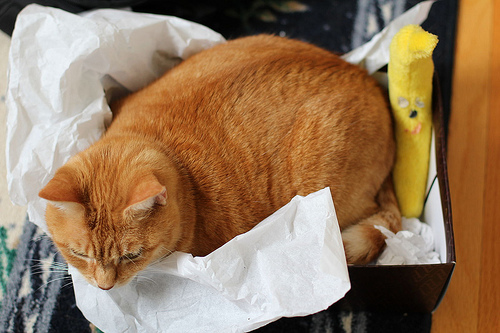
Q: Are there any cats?
A: Yes, there is a cat.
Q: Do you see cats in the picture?
A: Yes, there is a cat.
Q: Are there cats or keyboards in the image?
A: Yes, there is a cat.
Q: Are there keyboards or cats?
A: Yes, there is a cat.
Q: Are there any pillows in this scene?
A: No, there are no pillows.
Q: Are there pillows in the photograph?
A: No, there are no pillows.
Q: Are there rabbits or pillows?
A: No, there are no pillows or rabbits.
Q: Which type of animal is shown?
A: The animal is a cat.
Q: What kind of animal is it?
A: The animal is a cat.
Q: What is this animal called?
A: This is a cat.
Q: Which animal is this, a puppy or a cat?
A: This is a cat.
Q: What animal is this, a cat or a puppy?
A: This is a cat.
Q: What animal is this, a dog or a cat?
A: This is a cat.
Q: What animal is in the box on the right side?
A: The cat is in the box.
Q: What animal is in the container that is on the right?
A: The cat is in the box.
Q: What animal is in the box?
A: The cat is in the box.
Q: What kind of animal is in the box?
A: The animal is a cat.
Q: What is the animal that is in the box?
A: The animal is a cat.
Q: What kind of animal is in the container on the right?
A: The animal is a cat.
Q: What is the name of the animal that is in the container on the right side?
A: The animal is a cat.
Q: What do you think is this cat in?
A: The cat is in the box.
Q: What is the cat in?
A: The cat is in the box.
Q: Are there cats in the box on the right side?
A: Yes, there is a cat in the box.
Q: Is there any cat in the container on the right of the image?
A: Yes, there is a cat in the box.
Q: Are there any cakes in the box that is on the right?
A: No, there is a cat in the box.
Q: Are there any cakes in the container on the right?
A: No, there is a cat in the box.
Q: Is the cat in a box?
A: Yes, the cat is in a box.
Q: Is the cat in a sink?
A: No, the cat is in a box.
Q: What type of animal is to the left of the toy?
A: The animal is a cat.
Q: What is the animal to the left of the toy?
A: The animal is a cat.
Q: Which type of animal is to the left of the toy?
A: The animal is a cat.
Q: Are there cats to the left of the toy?
A: Yes, there is a cat to the left of the toy.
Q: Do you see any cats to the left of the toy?
A: Yes, there is a cat to the left of the toy.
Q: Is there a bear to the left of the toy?
A: No, there is a cat to the left of the toy.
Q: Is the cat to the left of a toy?
A: Yes, the cat is to the left of a toy.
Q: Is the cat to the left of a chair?
A: No, the cat is to the left of a toy.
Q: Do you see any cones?
A: No, there are no cones.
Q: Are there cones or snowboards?
A: No, there are no cones or snowboards.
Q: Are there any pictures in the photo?
A: No, there are no pictures.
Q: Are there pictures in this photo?
A: No, there are no pictures.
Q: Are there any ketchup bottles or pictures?
A: No, there are no pictures or ketchup bottles.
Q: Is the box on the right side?
A: Yes, the box is on the right of the image.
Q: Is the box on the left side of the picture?
A: No, the box is on the right of the image.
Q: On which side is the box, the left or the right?
A: The box is on the right of the image.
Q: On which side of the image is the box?
A: The box is on the right of the image.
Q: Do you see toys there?
A: Yes, there is a toy.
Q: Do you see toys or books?
A: Yes, there is a toy.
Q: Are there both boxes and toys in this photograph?
A: Yes, there are both a toy and a box.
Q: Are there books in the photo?
A: No, there are no books.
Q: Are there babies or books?
A: No, there are no books or babies.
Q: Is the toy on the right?
A: Yes, the toy is on the right of the image.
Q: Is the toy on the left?
A: No, the toy is on the right of the image.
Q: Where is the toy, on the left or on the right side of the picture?
A: The toy is on the right of the image.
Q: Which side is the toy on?
A: The toy is on the right of the image.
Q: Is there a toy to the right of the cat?
A: Yes, there is a toy to the right of the cat.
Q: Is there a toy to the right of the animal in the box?
A: Yes, there is a toy to the right of the cat.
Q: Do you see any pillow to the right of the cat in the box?
A: No, there is a toy to the right of the cat.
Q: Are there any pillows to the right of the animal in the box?
A: No, there is a toy to the right of the cat.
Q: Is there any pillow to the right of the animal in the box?
A: No, there is a toy to the right of the cat.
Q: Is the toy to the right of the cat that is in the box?
A: Yes, the toy is to the right of the cat.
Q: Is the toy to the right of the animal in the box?
A: Yes, the toy is to the right of the cat.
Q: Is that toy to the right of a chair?
A: No, the toy is to the right of the cat.